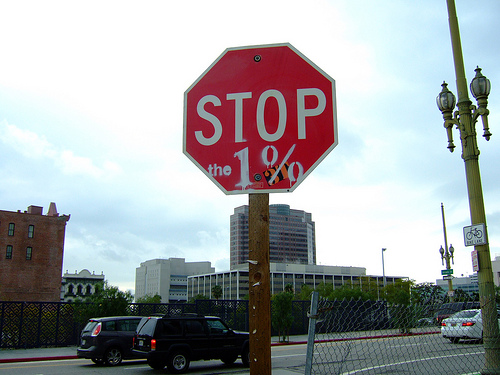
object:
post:
[248, 190, 271, 372]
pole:
[445, 1, 500, 375]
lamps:
[434, 79, 457, 155]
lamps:
[468, 66, 492, 143]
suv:
[65, 314, 132, 363]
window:
[8, 221, 15, 236]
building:
[0, 203, 72, 346]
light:
[462, 322, 468, 327]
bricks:
[290, 263, 317, 290]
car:
[434, 307, 488, 343]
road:
[1, 326, 498, 373]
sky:
[0, 6, 500, 268]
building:
[228, 202, 317, 269]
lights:
[441, 322, 447, 326]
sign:
[180, 40, 338, 199]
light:
[129, 336, 136, 346]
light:
[150, 338, 155, 350]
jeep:
[131, 305, 251, 372]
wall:
[4, 219, 60, 317]